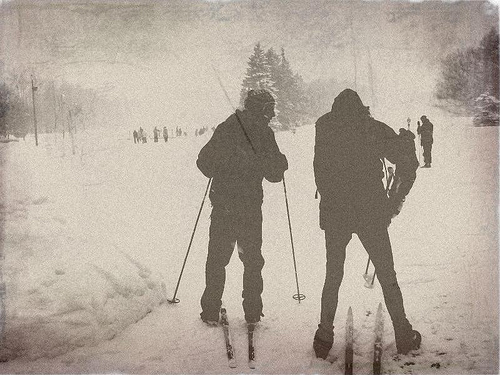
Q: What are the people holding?
A: Poles.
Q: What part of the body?
A: Legs.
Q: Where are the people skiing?
A: Outside in the snow.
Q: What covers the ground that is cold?
A: Snow.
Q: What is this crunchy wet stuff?
A: Snow.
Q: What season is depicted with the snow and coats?
A: Winter.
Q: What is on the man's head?
A: Hat.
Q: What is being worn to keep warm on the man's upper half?
A: Coat.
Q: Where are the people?
A: Ski resort.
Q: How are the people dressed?
A: For winter.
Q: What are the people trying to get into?
A: Skis.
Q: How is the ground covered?
A: With snow.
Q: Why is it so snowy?
A: Because it's snowing outside.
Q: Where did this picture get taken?
A: It was taken in the snow hills.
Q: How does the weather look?
A: It looks snowy.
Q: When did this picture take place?
A: It took place in the day time.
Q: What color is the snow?
A: The snow is white.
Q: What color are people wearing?
A: They are wearing black.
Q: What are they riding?
A: They are riding skis.